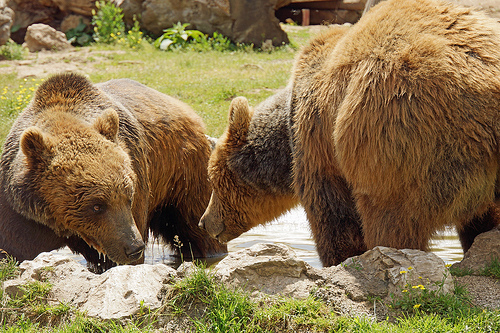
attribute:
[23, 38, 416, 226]
bears — together, brown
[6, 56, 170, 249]
bear — brown, wet, big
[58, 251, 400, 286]
rocks — grey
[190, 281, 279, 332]
grass — sparse, green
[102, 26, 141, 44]
flower — yellow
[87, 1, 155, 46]
flowers — yellow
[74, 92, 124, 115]
fur — rugged